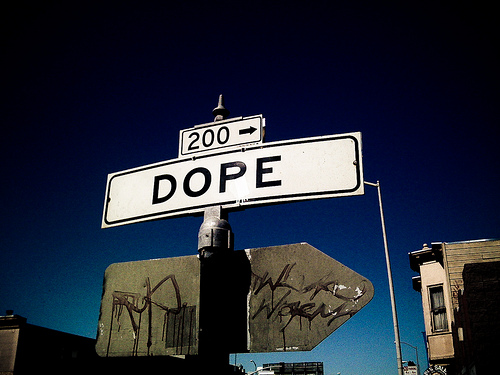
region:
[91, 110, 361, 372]
pole with black and white signs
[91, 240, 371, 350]
graffiti in back of pointed sign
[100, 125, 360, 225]
street sign of word with different meanings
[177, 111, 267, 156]
arrow to addresses at or above given number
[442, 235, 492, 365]
building covered with wooded planks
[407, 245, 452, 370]
narrow window on extended room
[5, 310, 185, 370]
low and flat building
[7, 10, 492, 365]
blue sky getting darker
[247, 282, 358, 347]
word with dripping ink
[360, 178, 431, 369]
long gray pole in front of building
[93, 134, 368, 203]
black lettering with white back ground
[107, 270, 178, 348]
grafitti on back of sign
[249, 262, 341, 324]
grafitti on back of sign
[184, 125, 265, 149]
black lettering on white sign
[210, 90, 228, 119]
metal fence topper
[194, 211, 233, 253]
pole topper with sign holder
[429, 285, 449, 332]
two pane window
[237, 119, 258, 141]
black directional arrow on white sign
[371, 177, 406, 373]
lamp post pole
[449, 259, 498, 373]
shadow of building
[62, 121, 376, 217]
a white street sign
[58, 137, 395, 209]
the white sign says Dope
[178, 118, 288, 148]
a smaller sign signaling the address numbers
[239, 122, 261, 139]
a black arrow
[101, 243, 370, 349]
graffiti on the back of a sign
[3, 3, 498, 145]
the sky is very dark and blue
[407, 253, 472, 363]
the window to a house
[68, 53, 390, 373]
a street sign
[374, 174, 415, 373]
a tall post to a street light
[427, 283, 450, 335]
there are white curtains in the window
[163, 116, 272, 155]
sign indicating the number two hundred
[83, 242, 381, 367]
back side of a one way street sign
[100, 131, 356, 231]
street sign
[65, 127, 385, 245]
street sign indicating the street named dope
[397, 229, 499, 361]
facade of an old building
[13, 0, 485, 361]
signs set against a clear blue sky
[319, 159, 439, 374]
metal utility pole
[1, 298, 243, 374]
old building against the sky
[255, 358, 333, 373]
old building against a sky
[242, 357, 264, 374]
street light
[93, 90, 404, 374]
street sign on a pole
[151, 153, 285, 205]
the word DOPE on a sign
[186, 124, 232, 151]
the number 200 on a sign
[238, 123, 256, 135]
black arrow on sign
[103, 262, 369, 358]
graffiti on back of sign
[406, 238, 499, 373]
building near the sign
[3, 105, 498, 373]
dark blue sky with no clouds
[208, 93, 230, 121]
pointed top of sign pole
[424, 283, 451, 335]
window on building near sign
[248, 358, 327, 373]
rooftop of a building